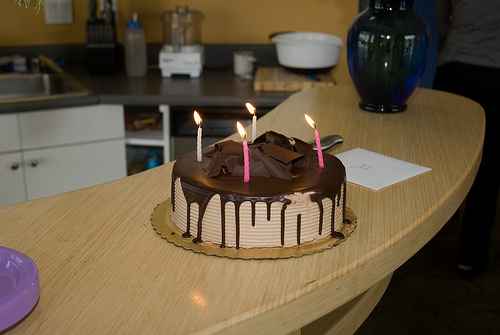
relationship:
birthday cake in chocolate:
[173, 125, 359, 250] [168, 130, 353, 252]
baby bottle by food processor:
[123, 11, 146, 76] [151, 2, 212, 76]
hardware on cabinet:
[29, 157, 41, 168] [0, 104, 128, 205]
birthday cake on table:
[173, 125, 359, 250] [0, 65, 497, 333]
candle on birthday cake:
[192, 124, 205, 159] [173, 125, 359, 250]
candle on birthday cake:
[248, 112, 256, 139] [173, 125, 359, 250]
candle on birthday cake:
[239, 141, 253, 178] [173, 125, 359, 250]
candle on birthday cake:
[313, 130, 324, 169] [173, 125, 359, 250]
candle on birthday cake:
[303, 112, 325, 169] [173, 125, 359, 250]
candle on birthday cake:
[243, 141, 251, 180] [173, 125, 359, 250]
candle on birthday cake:
[252, 116, 257, 142] [173, 125, 359, 250]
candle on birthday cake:
[196, 126, 203, 161] [173, 125, 359, 250]